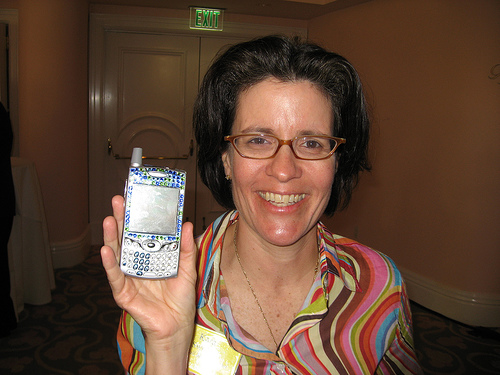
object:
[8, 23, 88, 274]
pillar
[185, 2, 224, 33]
sign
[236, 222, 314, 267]
neck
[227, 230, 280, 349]
chain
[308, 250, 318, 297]
chain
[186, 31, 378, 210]
dark hair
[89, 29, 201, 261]
door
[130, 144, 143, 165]
bar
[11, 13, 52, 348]
door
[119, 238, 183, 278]
buttons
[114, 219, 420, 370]
shirt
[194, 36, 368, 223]
hair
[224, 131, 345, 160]
glasses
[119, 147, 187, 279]
cell phone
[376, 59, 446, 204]
wall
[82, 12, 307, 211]
white doors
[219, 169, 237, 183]
earrings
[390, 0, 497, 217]
wall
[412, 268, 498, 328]
paneling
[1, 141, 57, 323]
coat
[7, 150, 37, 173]
knob